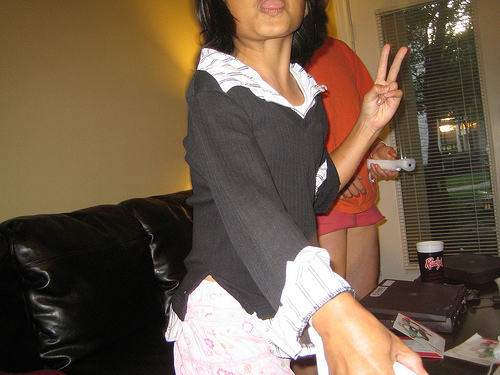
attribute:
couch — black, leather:
[7, 182, 171, 372]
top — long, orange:
[281, 28, 427, 218]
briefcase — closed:
[356, 278, 471, 333]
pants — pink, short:
[314, 202, 387, 237]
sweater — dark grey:
[157, 54, 349, 332]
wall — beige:
[40, 2, 160, 187]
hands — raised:
[338, 145, 400, 197]